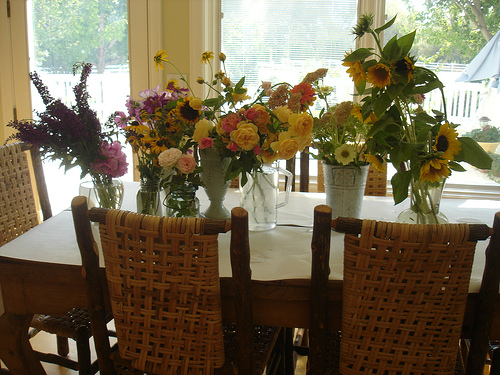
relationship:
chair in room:
[67, 201, 293, 373] [0, 0, 496, 371]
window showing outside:
[22, 0, 133, 221] [219, 0, 357, 80]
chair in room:
[70, 195, 302, 374] [0, 0, 496, 371]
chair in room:
[284, 186, 498, 348] [0, 0, 496, 371]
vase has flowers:
[321, 156, 371, 234] [301, 68, 384, 210]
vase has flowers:
[321, 156, 371, 234] [310, 9, 493, 187]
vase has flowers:
[319, 153, 374, 235] [275, 15, 491, 192]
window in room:
[22, 6, 142, 170] [0, 0, 496, 371]